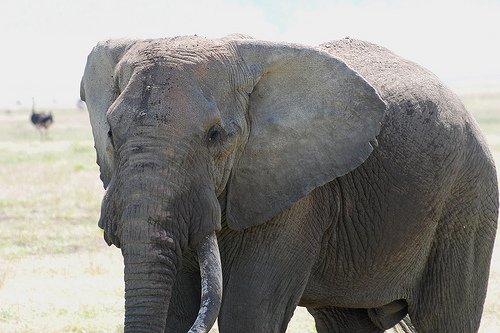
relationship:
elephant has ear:
[80, 35, 500, 331] [225, 41, 387, 231]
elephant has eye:
[80, 35, 500, 331] [210, 128, 221, 142]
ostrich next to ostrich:
[30, 95, 47, 141] [30, 95, 54, 141]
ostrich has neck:
[30, 95, 47, 141] [31, 100, 37, 112]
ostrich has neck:
[30, 95, 54, 141] [46, 101, 54, 115]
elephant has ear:
[80, 35, 500, 331] [79, 38, 133, 189]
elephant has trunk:
[80, 35, 500, 331] [113, 149, 193, 332]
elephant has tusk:
[80, 35, 500, 331] [184, 229, 223, 331]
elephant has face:
[80, 35, 500, 331] [98, 60, 244, 332]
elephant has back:
[80, 35, 500, 331] [307, 35, 469, 126]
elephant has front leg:
[80, 35, 500, 331] [219, 230, 317, 331]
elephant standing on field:
[80, 35, 500, 331] [2, 105, 126, 332]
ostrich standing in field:
[30, 95, 47, 141] [2, 105, 126, 332]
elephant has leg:
[80, 35, 500, 331] [406, 289, 487, 331]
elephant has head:
[80, 35, 500, 331] [80, 35, 390, 330]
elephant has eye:
[80, 35, 500, 331] [106, 123, 114, 143]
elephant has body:
[80, 35, 500, 331] [170, 38, 499, 330]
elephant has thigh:
[80, 35, 500, 331] [309, 307, 377, 331]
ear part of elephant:
[225, 41, 387, 231] [80, 35, 500, 331]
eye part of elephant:
[210, 128, 221, 142] [80, 35, 500, 331]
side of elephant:
[144, 38, 500, 331] [80, 35, 500, 331]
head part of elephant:
[80, 35, 390, 330] [80, 35, 500, 331]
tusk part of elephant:
[184, 229, 223, 331] [80, 35, 500, 331]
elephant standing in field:
[80, 35, 500, 331] [2, 105, 126, 332]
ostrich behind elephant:
[30, 95, 47, 141] [80, 35, 500, 331]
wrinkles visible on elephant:
[315, 154, 394, 286] [80, 35, 500, 331]